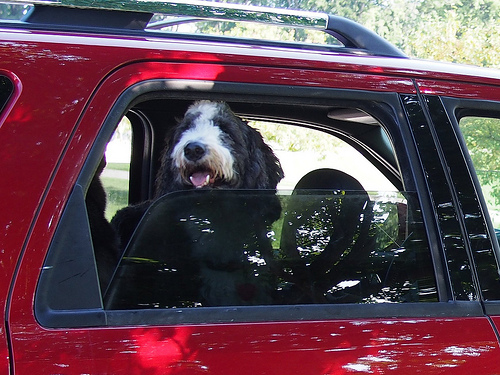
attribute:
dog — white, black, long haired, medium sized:
[160, 106, 300, 267]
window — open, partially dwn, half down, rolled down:
[101, 107, 421, 305]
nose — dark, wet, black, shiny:
[184, 144, 198, 163]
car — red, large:
[15, 23, 490, 350]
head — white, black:
[177, 113, 247, 190]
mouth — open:
[186, 168, 218, 191]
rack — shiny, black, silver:
[13, 7, 406, 62]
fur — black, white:
[222, 121, 264, 179]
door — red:
[22, 247, 482, 374]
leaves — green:
[416, 16, 473, 44]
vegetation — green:
[427, 12, 477, 55]